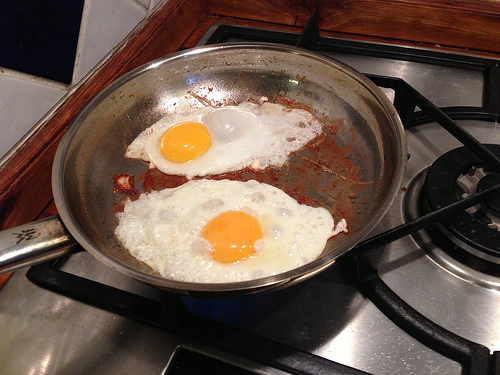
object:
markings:
[11, 228, 42, 245]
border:
[0, 44, 178, 232]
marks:
[320, 139, 365, 185]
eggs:
[114, 96, 350, 283]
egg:
[114, 179, 349, 284]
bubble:
[200, 109, 249, 144]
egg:
[123, 96, 326, 181]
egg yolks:
[199, 210, 262, 263]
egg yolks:
[158, 122, 213, 164]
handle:
[0, 214, 77, 274]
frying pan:
[0, 41, 408, 298]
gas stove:
[25, 22, 498, 375]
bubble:
[157, 203, 181, 222]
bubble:
[176, 255, 186, 263]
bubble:
[201, 198, 223, 212]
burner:
[418, 142, 500, 277]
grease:
[299, 157, 346, 194]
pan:
[0, 40, 406, 292]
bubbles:
[275, 208, 291, 219]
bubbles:
[268, 225, 282, 241]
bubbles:
[191, 237, 211, 255]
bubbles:
[179, 217, 208, 236]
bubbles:
[252, 192, 265, 204]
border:
[208, 2, 492, 55]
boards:
[161, 1, 209, 31]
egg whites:
[210, 97, 325, 175]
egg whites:
[138, 200, 202, 257]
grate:
[354, 330, 402, 375]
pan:
[0, 32, 421, 355]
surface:
[338, 66, 500, 375]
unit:
[363, 74, 500, 169]